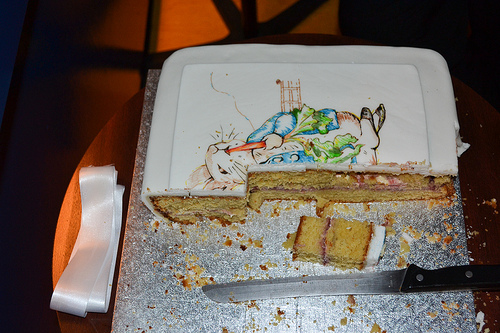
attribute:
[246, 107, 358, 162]
coat — blue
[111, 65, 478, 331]
tray — silver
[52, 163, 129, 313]
ribbon — white, thick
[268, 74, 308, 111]
fence — on the cake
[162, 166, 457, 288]
cake — sponge cake, yellow, soft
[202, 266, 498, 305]
knife — serrated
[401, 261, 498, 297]
handle — black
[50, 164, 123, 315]
ribbon — white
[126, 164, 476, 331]
cake — half-eaten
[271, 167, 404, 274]
cake — uneaten, small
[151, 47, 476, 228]
cake — on the plate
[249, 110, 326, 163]
coat — blue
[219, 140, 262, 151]
carrot — orange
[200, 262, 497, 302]
knife — long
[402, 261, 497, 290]
handle — black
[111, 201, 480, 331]
tray — foil, silver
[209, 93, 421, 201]
rabbit — design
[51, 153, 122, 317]
ribbon — white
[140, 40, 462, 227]
cake — on the plate, yellow, vanilla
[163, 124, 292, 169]
head — on the cake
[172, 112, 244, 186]
icing — vanilla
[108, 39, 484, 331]
cookie sheet — silver